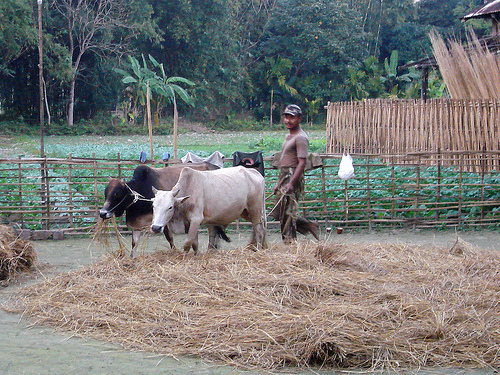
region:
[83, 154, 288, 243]
2 cows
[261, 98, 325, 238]
Man wearing tan shirt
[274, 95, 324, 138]
man wearing a hat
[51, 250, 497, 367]
straw on the ground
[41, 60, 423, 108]
green trees in the background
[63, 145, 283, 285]
2 cows walking and eating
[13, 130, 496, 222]
wood fence contain cows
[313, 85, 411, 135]
wood fence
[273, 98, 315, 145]
man has a dark mustache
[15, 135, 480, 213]
green plants beyond the fence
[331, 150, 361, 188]
white bag on fence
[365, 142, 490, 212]
wood fence in front of crop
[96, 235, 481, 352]
pile of hay on ground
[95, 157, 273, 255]
two oxen walking behind hay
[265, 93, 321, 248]
farmer wearing a cap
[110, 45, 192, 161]
two palm trees in the crop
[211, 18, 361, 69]
trees in the distance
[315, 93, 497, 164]
tall wood fence among crop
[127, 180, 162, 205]
rope tied on oxen neck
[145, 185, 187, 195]
horns on oxen head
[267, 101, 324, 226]
this is a man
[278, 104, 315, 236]
the man is walking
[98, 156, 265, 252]
these are two cows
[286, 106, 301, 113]
the man is wearing a cap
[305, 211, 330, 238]
the man is bare booted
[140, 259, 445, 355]
the hay is brown in color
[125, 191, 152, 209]
the cows are tied by rope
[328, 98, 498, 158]
the fence is wooden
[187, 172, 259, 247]
the cow is cream in color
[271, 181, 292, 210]
the man is holding a stick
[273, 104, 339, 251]
An Asian man holding rope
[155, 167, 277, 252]
a white cow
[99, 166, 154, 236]
a black cow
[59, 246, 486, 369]
dry hay on the ground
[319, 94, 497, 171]
a sheet of wood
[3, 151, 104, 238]
a wooden fence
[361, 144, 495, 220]
vegetation on a farm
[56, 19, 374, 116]
a forest in the background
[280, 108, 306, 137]
a man with a hat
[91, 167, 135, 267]
cow eating some hay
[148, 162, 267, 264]
white cow standing on hay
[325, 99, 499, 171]
fence made of wooden sticks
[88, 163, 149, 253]
brown cow eating hay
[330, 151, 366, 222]
plastic bag hanging on the fence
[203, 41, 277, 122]
forest in the background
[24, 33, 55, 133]
tree trunk in the background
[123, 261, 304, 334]
hay lying on the ground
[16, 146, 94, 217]
vegetable garden behind the fence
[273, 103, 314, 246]
man in a brown t-shirt and dark pants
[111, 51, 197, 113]
palm trees in the background